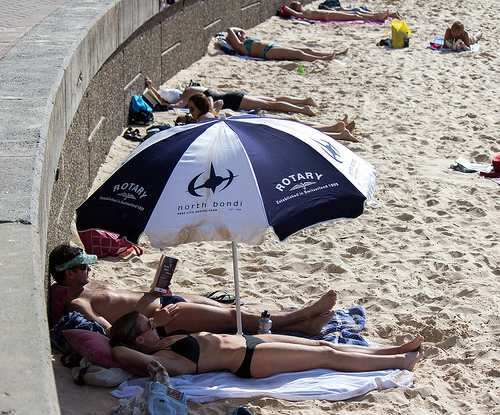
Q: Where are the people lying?
A: On the beach.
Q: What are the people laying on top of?
A: Towels.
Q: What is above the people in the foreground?
A: Beach umbrella.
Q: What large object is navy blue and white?
A: Beach umbrella.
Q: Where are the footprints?
A: In the sand.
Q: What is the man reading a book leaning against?
A: A cement wall.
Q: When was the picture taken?
A: Sunny day.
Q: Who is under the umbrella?
A: A man and a woman.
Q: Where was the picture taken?
A: On a beach.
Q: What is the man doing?
A: Reading a book.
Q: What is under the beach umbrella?
A: A hey lounge.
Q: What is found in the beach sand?
A: Footprints.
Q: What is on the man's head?
A: A cap.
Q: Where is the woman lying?
A: On the sand.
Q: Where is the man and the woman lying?
A: Under the umbrella.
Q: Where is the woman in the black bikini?
A: At the beach.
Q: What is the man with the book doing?
A: Reading a book,.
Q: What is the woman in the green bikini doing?
A: Sunbathing.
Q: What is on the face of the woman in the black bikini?
A: Sunglasses.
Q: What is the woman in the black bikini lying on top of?
A: Towel.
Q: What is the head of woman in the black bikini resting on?
A: Pillow.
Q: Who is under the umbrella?
A: Man and woman.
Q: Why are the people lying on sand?
A: Sunbathing.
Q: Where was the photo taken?
A: Beach.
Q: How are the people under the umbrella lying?
A: Facing up.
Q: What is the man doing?
A: Reading a book.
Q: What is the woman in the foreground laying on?
A: Beach towel.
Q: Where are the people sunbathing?
A: Beach.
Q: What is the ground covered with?
A: Sand.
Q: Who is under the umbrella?
A: A couple.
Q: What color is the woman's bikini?
A: Black.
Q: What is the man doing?
A: Reading a book.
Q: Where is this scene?
A: At the beach.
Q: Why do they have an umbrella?
A: For shade.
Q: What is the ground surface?
A: Sand.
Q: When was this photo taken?
A: During the daytime.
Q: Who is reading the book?
A: The man.